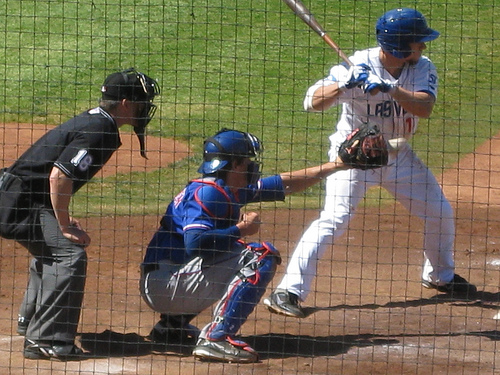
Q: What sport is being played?
A: Baseball.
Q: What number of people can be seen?
A: Three.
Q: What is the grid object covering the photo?
A: A net.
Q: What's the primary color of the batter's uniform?
A: White.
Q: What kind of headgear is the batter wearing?
A: A helmet.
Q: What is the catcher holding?
A: A glove.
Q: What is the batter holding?
A: A bat.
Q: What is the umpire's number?
A: 18.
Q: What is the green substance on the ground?
A: Grass.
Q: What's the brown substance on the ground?
A: Dirt.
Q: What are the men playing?
A: Baseball.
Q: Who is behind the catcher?
A: Umpire.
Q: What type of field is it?
A: Baseball.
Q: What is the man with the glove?
A: Catcher.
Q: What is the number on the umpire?
A: 18.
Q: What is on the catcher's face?
A: Mask.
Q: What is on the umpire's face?
A: Mask.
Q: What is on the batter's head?
A: Helmet.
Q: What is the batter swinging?
A: Bat.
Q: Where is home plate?
A: Dirt.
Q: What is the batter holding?
A: A bat.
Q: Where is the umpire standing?
A: Behind the catcher.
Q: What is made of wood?
A: Baseball bat.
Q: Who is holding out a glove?
A: Catcher.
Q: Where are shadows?
A: On the dirt.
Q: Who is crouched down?
A: The catcher.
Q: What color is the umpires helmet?
A: Black.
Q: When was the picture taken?
A: Daytime.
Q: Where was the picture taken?
A: Ballpark.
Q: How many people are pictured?
A: 3.